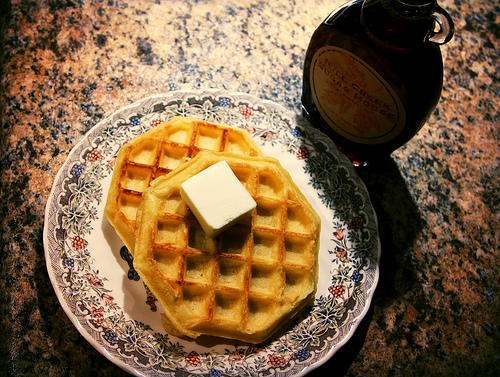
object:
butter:
[153, 173, 179, 201]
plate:
[43, 89, 382, 377]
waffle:
[104, 116, 321, 345]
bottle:
[300, 0, 454, 156]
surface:
[1, 0, 498, 376]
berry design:
[70, 163, 85, 177]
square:
[252, 228, 279, 261]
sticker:
[310, 45, 406, 144]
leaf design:
[57, 201, 90, 238]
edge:
[308, 215, 319, 301]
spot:
[136, 38, 154, 56]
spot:
[224, 6, 239, 17]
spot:
[241, 42, 254, 58]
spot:
[215, 66, 224, 73]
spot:
[93, 33, 106, 49]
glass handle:
[429, 3, 455, 45]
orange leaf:
[310, 46, 407, 145]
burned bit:
[121, 158, 157, 169]